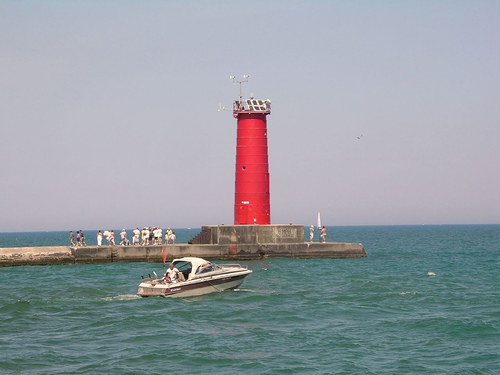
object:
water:
[0, 224, 500, 373]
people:
[79, 229, 88, 246]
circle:
[241, 166, 247, 170]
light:
[243, 73, 250, 79]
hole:
[242, 166, 245, 170]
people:
[120, 229, 128, 246]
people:
[141, 228, 149, 246]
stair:
[186, 222, 207, 243]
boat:
[315, 211, 324, 230]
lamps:
[229, 76, 236, 80]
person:
[165, 262, 180, 284]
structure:
[233, 93, 271, 119]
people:
[65, 229, 76, 248]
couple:
[164, 263, 182, 284]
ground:
[355, 87, 380, 114]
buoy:
[424, 268, 436, 277]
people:
[96, 230, 103, 247]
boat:
[135, 252, 253, 302]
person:
[248, 88, 255, 109]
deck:
[230, 94, 273, 116]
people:
[73, 230, 84, 247]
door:
[233, 201, 251, 226]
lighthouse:
[228, 72, 273, 225]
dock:
[0, 224, 367, 262]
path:
[0, 246, 71, 252]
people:
[131, 227, 140, 246]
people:
[107, 230, 115, 246]